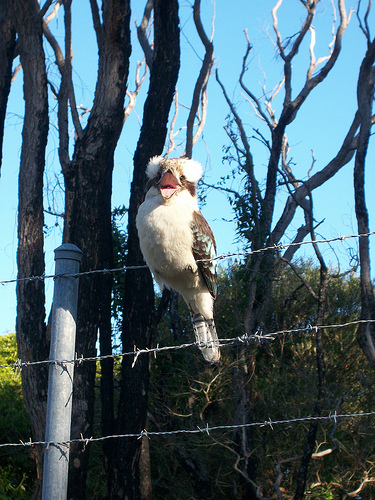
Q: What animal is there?
A: Bird.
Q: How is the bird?
A: Perched.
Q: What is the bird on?
A: Barbed wire.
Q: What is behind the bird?
A: Trees.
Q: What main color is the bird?
A: White.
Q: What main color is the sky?
A: Blue.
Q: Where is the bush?
A: Background.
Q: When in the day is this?
A: Afternoon.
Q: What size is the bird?
A: Large.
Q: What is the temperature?
A: Cool.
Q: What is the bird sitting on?
A: Barbed wire.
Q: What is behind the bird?
A: Trees.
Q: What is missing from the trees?
A: Leaves.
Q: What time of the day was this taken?
A: In the daytime.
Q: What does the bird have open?
A: Beak.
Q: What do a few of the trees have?
A: Green leaves.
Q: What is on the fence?
A: Bird.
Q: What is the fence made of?
A: Metal.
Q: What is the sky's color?
A: Blue.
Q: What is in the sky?
A: Nothing.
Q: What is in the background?
A: Trees.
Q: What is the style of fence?
A: Barb wired.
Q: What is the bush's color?
A: Green.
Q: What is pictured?
A: A Bird.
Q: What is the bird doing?
A: Sitting on barbed wire.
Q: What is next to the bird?
A: A Pole.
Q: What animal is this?
A: Bird.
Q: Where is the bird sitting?
A: Fence.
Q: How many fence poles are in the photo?
A: One.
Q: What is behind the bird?
A: Trees.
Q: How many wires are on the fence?
A: Three.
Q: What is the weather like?
A: Sunny.